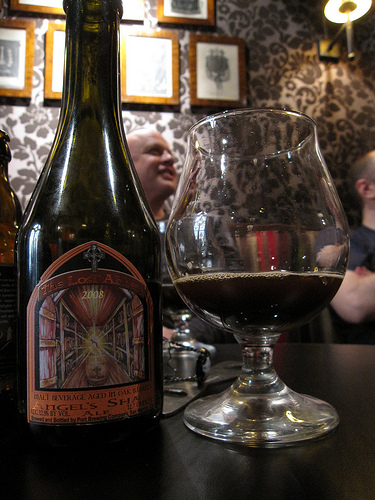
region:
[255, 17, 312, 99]
Brown flowered wall paper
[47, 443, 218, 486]
Wood table top surface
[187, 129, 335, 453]
Glass partially filled with dark beverage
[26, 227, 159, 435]
Label on side of glass bottle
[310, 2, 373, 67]
Wall mounted light fixture with shade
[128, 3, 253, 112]
Wood frames pictures hanging on wall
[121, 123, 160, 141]
Light reflected off top of mans head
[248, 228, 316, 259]
Striped pattern on back of chair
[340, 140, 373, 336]
Man in black shirt and crossed arms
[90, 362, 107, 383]
Cross in middle of bottle lable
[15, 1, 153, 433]
the bottle of wine on the table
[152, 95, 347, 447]
the glass of wine on the table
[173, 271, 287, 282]
bubbles in the wine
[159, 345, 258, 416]
the bottle opener on the table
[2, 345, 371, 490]
the table is wood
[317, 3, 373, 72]
the light on the wall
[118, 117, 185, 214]
the man is smiling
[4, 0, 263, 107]
pictures hanging on the wall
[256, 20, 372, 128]
the wall is patterned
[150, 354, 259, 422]
the bottle opener is metal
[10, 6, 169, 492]
A wine bottle made from dark glass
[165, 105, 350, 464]
wine glass with dark liquid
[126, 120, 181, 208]
a man with no hair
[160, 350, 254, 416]
metal bottle opener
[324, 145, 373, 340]
man with his arms folded in front of him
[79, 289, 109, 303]
date 2008 printed on the label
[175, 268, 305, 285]
bubbles on top of the liquid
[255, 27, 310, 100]
flower patterned wall paper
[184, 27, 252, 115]
wooden framed picture on the wall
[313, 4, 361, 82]
a light fixture on the wall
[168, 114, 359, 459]
Glass on a table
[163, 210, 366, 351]
Wine in a glass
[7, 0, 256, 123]
Photo frames on the wall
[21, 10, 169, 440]
Wine bottle on the table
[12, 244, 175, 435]
Label on the bottle of wine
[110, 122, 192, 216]
Bald man's head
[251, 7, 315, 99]
Wallpaper on the wall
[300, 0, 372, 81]
Light fixture on the wall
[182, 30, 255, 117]
Wood surrounding photo frame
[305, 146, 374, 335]
Man with arms crossed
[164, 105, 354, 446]
Cup of glass next to bottle of beer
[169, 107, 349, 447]
Cup of glass has brown liquid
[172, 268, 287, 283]
Bubbles on brown liquid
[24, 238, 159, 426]
Tag on beer bottle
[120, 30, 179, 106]
Wooden art on wall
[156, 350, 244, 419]
Beer opener behind beer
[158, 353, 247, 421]
Beer opened behind glass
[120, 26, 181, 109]
Wooden art above man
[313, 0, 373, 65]
Light is lit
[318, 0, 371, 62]
Lamp near wooden art